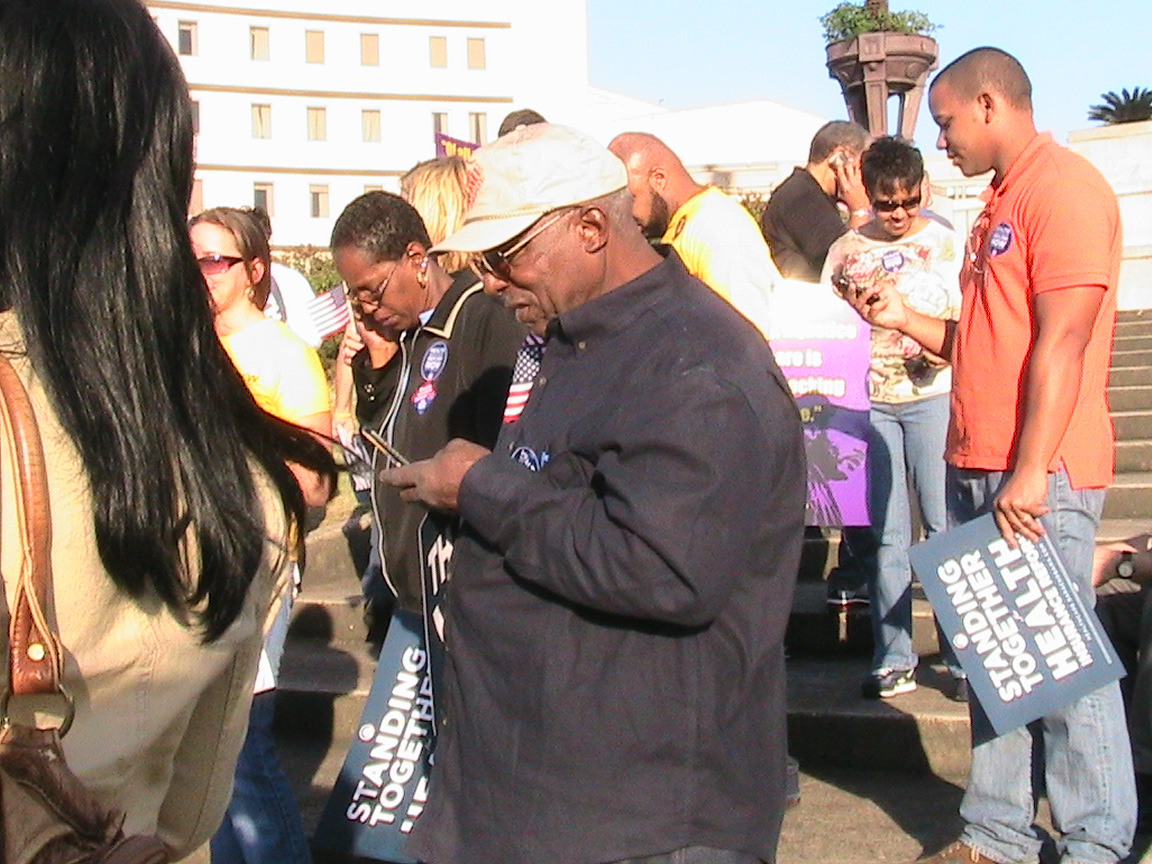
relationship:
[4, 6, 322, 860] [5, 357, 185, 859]
person wearing bag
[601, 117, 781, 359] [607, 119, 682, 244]
man with head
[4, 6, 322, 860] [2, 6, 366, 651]
person with hair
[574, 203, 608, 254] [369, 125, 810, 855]
ear of man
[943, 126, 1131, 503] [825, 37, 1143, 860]
shirt on man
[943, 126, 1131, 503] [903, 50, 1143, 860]
shirt on man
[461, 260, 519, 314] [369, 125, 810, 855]
nose on man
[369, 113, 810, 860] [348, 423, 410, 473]
person using cell phone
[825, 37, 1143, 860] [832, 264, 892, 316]
man using cell phone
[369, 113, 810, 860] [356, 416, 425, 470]
person using cell phone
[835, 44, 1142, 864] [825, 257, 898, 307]
man using cell phone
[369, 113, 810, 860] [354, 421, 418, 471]
person using cell phone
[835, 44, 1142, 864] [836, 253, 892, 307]
man using cell phone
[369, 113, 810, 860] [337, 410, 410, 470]
person using cell phone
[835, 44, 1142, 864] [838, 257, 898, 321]
man using cell phone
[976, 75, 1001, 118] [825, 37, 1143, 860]
ear on man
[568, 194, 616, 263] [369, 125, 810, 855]
ear on man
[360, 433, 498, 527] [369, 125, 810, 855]
hand on man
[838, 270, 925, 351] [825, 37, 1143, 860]
hand on man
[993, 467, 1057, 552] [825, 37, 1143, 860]
hand on man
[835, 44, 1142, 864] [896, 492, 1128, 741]
man holding sign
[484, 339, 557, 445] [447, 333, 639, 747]
flag on shirt